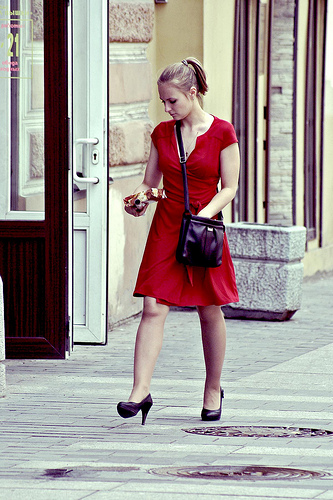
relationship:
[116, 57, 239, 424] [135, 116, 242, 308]
woman wearing red dress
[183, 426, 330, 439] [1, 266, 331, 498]
manhole cover on sidewalk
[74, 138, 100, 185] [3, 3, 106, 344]
handle on door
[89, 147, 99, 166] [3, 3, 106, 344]
keyhole on door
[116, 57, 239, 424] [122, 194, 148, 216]
woman looking at hand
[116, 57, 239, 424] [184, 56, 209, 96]
woman with ponytail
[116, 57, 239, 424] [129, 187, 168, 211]
woman holding paper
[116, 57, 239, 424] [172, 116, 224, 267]
woman holding black purse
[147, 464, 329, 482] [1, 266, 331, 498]
manhole cover on sidewalk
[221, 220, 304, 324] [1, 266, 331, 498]
planter on sidewalk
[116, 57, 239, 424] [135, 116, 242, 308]
woman in red dress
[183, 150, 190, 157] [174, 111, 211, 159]
cross on necklace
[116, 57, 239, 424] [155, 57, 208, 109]
woman with blonde hair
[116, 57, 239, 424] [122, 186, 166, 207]
woman carrying wrapped package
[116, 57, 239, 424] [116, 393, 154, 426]
woman wearing black shoe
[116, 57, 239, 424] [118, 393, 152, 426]
woman weariheelg black shoe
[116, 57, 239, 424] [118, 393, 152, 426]
woman with black shoe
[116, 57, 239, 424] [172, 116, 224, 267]
woman with black purse